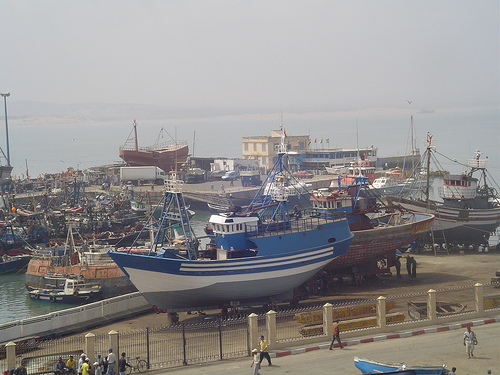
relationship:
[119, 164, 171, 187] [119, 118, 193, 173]
truck in front of ship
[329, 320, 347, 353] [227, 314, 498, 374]
person walking at boat dock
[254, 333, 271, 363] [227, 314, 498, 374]
person walking at boat dock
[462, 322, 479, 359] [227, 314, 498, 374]
person walking at boat dock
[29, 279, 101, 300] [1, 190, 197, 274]
boat on barge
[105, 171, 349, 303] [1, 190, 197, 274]
boats on barge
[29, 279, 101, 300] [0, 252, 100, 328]
boat on water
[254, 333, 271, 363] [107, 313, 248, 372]
person standing and walking by railing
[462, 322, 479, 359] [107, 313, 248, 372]
person standing and walking by railing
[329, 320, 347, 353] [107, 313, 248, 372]
person standing and walking by railing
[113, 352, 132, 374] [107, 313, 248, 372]
person standing and walking by railing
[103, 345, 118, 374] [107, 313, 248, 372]
person standing and walking by railing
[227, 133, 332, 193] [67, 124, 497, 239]
building on harbor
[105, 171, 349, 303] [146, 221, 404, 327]
boats near dock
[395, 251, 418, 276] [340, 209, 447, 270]
workers under boat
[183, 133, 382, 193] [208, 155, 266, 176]
building next to building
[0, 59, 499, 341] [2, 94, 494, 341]
construction area behind construction area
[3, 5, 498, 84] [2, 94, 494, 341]
sky behind construction area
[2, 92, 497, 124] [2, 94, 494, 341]
land behind construction area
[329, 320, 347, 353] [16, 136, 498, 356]
person walking at a boat dock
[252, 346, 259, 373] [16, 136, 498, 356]
person walking at a boat dock